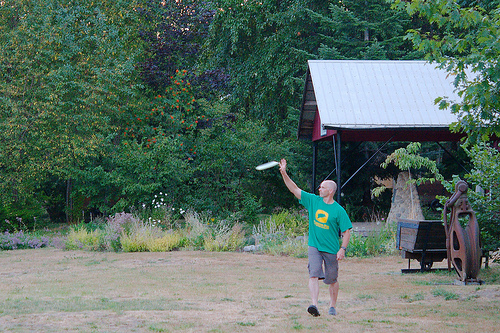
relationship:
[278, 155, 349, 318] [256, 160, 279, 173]
man catching frisbee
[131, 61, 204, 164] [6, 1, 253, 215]
red flowers on tree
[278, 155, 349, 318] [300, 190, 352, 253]
man wearing green shirt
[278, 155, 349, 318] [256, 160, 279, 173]
man playing frisbee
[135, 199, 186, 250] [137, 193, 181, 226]
bush has white flowers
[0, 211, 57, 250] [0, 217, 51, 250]
bush has bush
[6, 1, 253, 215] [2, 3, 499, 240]
trees in background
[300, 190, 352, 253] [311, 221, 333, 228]
shirt has yellow letters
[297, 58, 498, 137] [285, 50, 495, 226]
white roof on barn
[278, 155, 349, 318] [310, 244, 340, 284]
man wearing shorts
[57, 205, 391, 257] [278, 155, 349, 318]
grass behind man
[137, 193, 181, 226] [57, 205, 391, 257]
white flowers in grass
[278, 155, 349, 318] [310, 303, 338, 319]
man has shoes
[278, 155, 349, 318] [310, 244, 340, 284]
man has gray shorts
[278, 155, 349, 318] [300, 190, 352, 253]
man has on a green shirt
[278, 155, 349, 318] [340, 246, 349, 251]
man wearing watch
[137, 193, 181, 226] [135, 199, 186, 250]
white flowers on bush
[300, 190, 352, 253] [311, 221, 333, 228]
green shirt has yellow letters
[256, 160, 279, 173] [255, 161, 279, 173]
frisbee colored white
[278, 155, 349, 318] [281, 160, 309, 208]
man waving arm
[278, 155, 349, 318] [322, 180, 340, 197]
man has shaved head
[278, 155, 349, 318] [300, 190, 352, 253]
man has green shirt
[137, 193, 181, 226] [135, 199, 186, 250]
white flowers by bush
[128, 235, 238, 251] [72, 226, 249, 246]
orange leaves on bushes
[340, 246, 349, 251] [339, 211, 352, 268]
watch on left arm